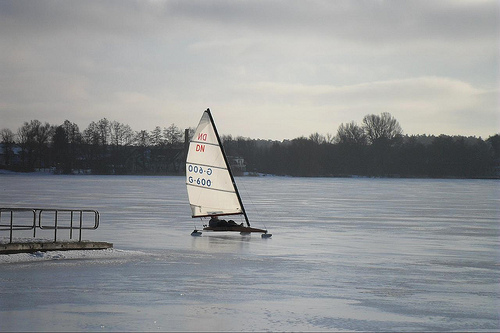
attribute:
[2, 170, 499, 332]
water — dark, frozen, pale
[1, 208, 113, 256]
dock — metal, concrete, grey, cement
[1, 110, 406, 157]
trees — bare, evergreen, tall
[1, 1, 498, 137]
sky — cloudy, overcast, grey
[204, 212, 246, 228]
man — shadowed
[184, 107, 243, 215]
sail — white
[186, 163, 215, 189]
letters — blue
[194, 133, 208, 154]
letters — red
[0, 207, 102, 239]
handrail — metal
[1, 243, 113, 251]
sidewalk — cement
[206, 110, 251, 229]
mast — black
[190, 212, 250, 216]
boom — black